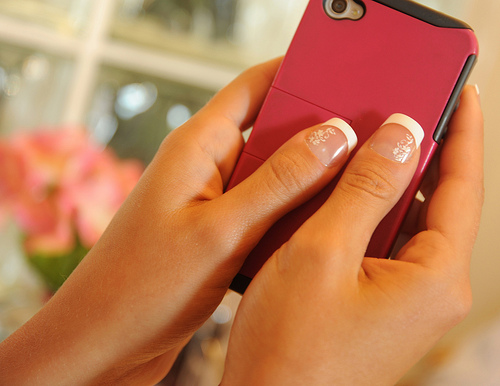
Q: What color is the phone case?
A: Red.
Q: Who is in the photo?
A: A woman.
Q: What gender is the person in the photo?
A: Female.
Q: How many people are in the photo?
A: One.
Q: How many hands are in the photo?
A: Two.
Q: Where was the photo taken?
A: In the living room.